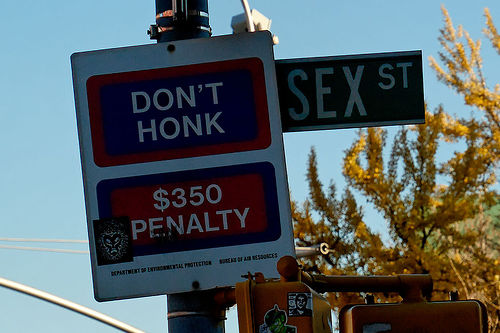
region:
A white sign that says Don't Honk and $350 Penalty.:
[68, 27, 300, 299]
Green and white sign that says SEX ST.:
[273, 48, 427, 130]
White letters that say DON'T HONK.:
[130, 80, 227, 142]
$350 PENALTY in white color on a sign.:
[127, 185, 250, 240]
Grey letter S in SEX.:
[286, 68, 310, 120]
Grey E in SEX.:
[315, 65, 337, 117]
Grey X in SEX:
[339, 63, 366, 120]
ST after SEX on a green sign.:
[376, 60, 413, 90]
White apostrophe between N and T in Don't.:
[197, 83, 204, 93]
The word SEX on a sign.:
[287, 63, 366, 120]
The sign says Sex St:
[270, 48, 455, 130]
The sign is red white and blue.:
[75, 45, 305, 275]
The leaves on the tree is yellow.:
[356, 135, 456, 242]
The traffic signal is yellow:
[225, 260, 456, 327]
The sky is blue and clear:
[12, 23, 78, 194]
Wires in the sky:
[9, 225, 89, 265]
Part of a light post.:
[6, 273, 87, 319]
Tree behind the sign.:
[334, 133, 479, 275]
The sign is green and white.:
[284, 45, 439, 141]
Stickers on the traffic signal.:
[264, 293, 294, 323]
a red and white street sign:
[277, 49, 422, 131]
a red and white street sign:
[68, 35, 293, 283]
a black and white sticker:
[261, 304, 293, 329]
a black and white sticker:
[288, 290, 311, 311]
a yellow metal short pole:
[317, 272, 436, 299]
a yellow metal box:
[234, 275, 335, 331]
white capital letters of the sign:
[129, 206, 258, 238]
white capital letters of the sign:
[132, 84, 221, 112]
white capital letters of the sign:
[137, 112, 230, 142]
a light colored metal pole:
[0, 274, 143, 331]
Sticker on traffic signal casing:
[284, 286, 312, 318]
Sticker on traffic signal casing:
[253, 303, 298, 331]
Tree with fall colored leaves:
[289, 0, 496, 327]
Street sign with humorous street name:
[274, 49, 430, 133]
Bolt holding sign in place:
[165, 42, 180, 56]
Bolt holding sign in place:
[188, 278, 202, 290]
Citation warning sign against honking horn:
[66, 29, 301, 304]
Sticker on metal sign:
[91, 211, 138, 269]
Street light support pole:
[1, 270, 149, 332]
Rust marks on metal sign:
[203, 281, 237, 295]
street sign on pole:
[291, 52, 426, 128]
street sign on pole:
[85, 36, 289, 281]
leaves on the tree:
[410, 213, 428, 232]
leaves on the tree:
[370, 169, 386, 193]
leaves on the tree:
[328, 207, 342, 227]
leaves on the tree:
[466, 267, 488, 296]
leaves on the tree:
[324, 226, 350, 249]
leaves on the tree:
[478, 147, 490, 168]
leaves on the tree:
[443, 119, 466, 141]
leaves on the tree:
[319, 196, 339, 221]